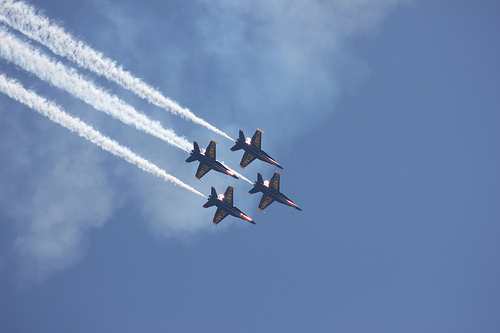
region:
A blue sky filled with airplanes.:
[0, 5, 497, 331]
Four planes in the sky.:
[186, 126, 308, 228]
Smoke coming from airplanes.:
[2, 1, 252, 203]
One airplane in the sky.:
[202, 181, 257, 227]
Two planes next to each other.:
[183, 124, 285, 177]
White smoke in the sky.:
[202, 6, 394, 106]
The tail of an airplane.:
[227, 127, 248, 153]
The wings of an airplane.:
[210, 183, 240, 229]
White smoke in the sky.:
[2, 4, 252, 207]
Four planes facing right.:
[180, 118, 305, 228]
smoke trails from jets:
[0, 6, 252, 199]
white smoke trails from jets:
[0, 0, 253, 197]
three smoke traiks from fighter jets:
[1, 0, 252, 199]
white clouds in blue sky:
[4, 1, 405, 286]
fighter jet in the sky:
[183, 139, 242, 182]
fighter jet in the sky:
[201, 185, 254, 225]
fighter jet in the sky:
[246, 173, 302, 212]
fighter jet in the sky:
[229, 129, 284, 169]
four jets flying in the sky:
[187, 127, 305, 227]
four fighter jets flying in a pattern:
[183, 127, 303, 224]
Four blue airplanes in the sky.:
[180, 121, 305, 229]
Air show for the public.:
[18, 21, 458, 296]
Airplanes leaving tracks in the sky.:
[2, 0, 179, 189]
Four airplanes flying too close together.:
[183, 130, 307, 231]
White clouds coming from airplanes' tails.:
[0, 62, 187, 185]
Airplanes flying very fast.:
[188, 128, 309, 228]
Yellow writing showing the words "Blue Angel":
[251, 169, 301, 212]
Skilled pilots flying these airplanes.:
[182, 126, 309, 230]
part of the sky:
[370, 184, 387, 196]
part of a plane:
[291, 188, 298, 215]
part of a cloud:
[281, 133, 299, 163]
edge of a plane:
[230, 212, 242, 229]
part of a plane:
[248, 220, 250, 223]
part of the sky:
[335, 218, 343, 227]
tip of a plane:
[231, 208, 241, 223]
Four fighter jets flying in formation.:
[182, 124, 306, 231]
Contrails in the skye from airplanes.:
[80, 52, 176, 169]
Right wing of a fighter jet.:
[219, 184, 240, 206]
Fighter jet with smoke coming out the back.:
[246, 170, 306, 214]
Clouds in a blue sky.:
[30, 190, 118, 242]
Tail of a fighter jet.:
[184, 139, 203, 166]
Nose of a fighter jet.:
[235, 206, 260, 228]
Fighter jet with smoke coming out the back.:
[194, 184, 254, 229]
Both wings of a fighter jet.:
[239, 125, 264, 168]